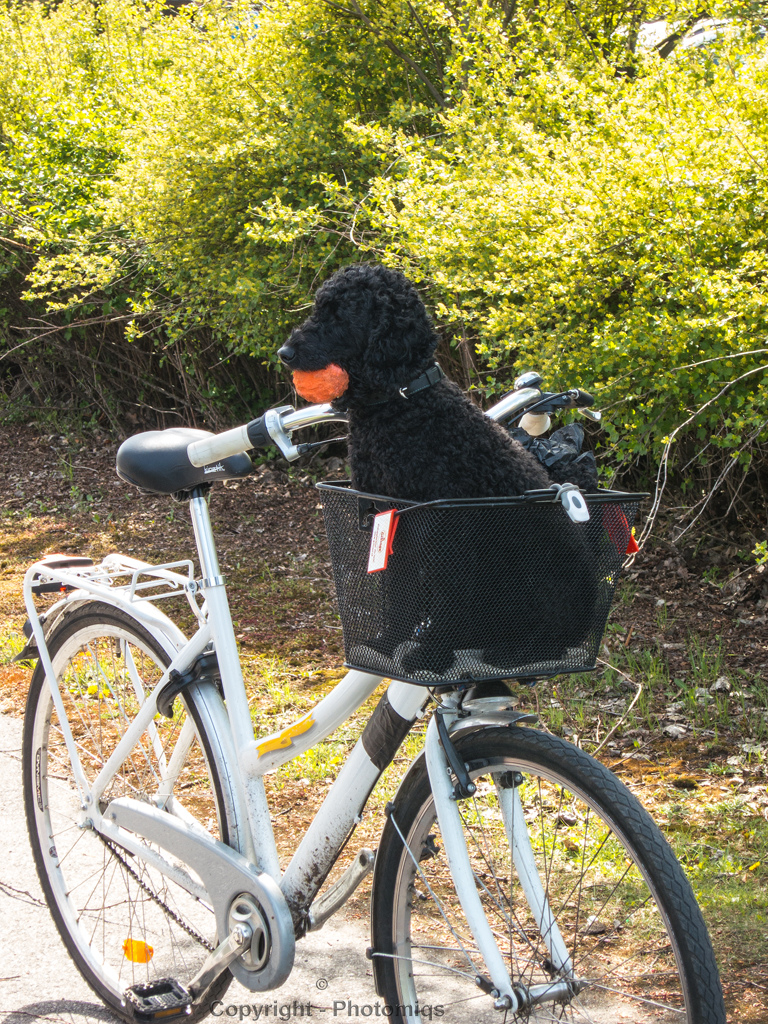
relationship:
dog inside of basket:
[264, 272, 545, 511] [318, 466, 650, 685]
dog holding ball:
[264, 272, 545, 511] [301, 334, 380, 418]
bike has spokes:
[48, 443, 484, 963] [492, 820, 647, 955]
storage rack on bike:
[37, 505, 206, 643] [48, 443, 484, 963]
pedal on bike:
[129, 964, 211, 1020] [48, 443, 484, 963]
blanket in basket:
[363, 620, 543, 690] [318, 466, 650, 685]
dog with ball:
[264, 272, 545, 511] [301, 334, 380, 418]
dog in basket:
[264, 272, 545, 511] [318, 466, 650, 685]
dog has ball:
[264, 272, 545, 511] [301, 334, 380, 418]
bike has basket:
[48, 443, 484, 963] [318, 466, 650, 685]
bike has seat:
[48, 443, 484, 963] [101, 381, 250, 516]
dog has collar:
[264, 272, 545, 511] [385, 348, 447, 421]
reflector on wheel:
[98, 930, 188, 975] [3, 564, 276, 1006]